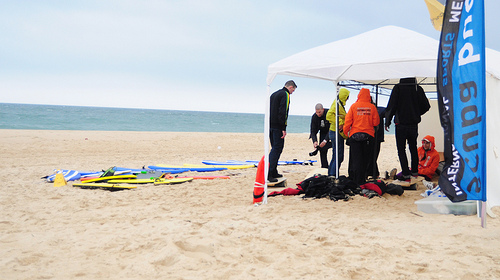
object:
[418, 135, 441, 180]
orange jacket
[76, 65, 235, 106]
clouds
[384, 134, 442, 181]
man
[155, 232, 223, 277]
tracks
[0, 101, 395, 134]
ocean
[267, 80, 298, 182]
man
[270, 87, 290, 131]
shirt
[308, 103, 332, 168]
man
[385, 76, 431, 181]
man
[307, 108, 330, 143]
wetsuit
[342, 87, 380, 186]
people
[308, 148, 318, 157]
socks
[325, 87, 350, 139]
jacket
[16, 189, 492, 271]
sand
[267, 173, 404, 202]
equipment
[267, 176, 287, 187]
surfboard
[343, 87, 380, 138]
hooded jacket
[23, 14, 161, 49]
clouds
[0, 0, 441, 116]
sky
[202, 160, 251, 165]
surfboard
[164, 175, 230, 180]
surfboard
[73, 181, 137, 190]
surfboard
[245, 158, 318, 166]
surfboard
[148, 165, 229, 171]
surfboard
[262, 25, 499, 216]
canopy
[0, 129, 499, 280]
beach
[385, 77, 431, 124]
clothing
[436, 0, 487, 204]
banner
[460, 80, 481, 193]
text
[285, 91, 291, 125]
lines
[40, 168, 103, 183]
equipment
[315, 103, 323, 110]
hair